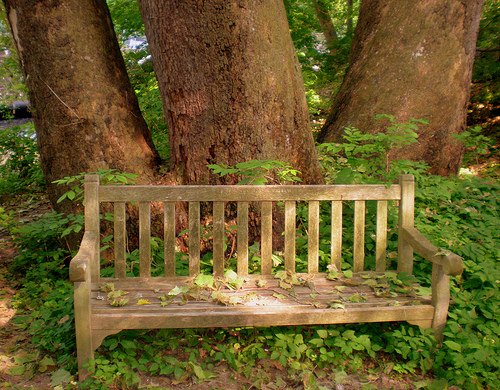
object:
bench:
[68, 174, 463, 372]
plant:
[210, 335, 313, 372]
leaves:
[194, 269, 237, 306]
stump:
[44, 169, 321, 253]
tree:
[3, 0, 327, 259]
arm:
[401, 222, 465, 304]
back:
[99, 184, 400, 277]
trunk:
[145, 11, 324, 165]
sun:
[456, 165, 484, 180]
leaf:
[432, 246, 451, 257]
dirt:
[215, 367, 247, 389]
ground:
[27, 332, 329, 389]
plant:
[337, 122, 411, 168]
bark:
[132, 128, 160, 165]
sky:
[119, 27, 146, 53]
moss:
[442, 42, 463, 70]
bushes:
[345, 128, 484, 360]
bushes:
[117, 24, 178, 154]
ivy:
[460, 193, 482, 359]